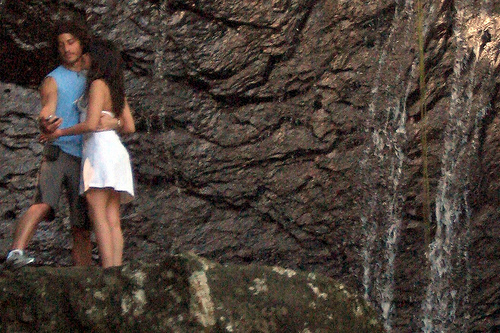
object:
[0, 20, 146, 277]
couple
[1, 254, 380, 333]
rock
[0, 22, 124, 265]
man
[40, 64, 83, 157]
shirt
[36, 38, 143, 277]
lady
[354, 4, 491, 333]
water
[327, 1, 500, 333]
rock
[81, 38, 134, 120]
hair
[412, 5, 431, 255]
growth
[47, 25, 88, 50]
hair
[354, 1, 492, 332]
waterfall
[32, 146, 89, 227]
shorts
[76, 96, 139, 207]
dress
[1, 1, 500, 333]
rock wall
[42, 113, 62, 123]
phone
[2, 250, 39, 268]
sneakers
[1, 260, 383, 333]
moss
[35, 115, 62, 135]
hand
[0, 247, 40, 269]
foot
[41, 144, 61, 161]
phone holder